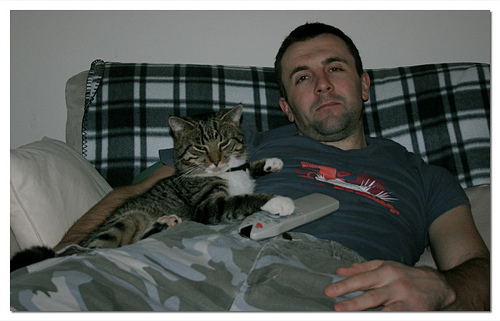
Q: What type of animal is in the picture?
A: A cat.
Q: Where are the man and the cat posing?
A: On a couch.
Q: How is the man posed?
A: Slouching.